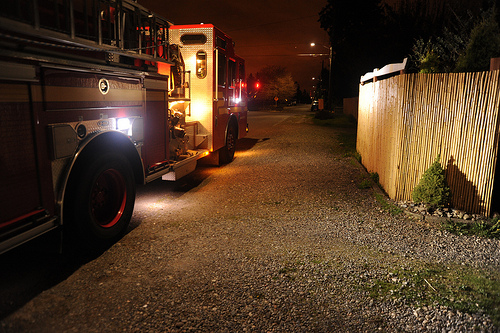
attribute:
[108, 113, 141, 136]
light — shining, red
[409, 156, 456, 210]
tree — green, small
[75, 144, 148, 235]
tire — red, black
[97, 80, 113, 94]
cap — gas, silver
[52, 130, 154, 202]
fender — metal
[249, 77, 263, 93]
signal — street, red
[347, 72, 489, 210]
fence — wooden, tall, brown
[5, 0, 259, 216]
truck — red, fire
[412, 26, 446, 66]
plant — green, small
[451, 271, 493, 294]
grass — green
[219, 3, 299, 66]
sky — dark